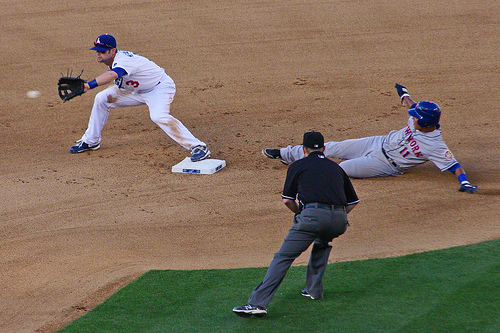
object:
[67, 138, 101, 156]
cleats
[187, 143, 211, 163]
cleats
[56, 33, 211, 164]
fielder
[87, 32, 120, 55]
hat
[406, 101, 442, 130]
helmet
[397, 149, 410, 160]
number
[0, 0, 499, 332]
scene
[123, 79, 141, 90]
number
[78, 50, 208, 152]
uniform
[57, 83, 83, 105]
glove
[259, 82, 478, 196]
runner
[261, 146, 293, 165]
shoes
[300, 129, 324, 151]
hat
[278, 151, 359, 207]
shirt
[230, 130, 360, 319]
umpire